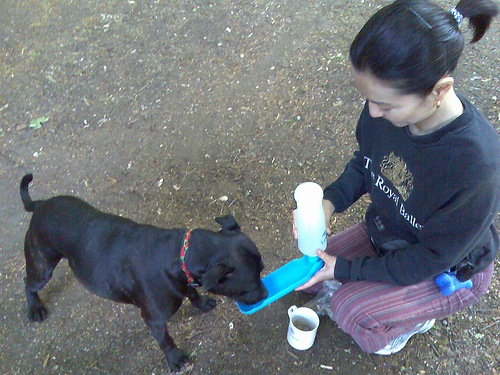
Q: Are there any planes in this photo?
A: No, there are no planes.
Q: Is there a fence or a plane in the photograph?
A: No, there are no airplanes or fences.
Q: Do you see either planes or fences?
A: No, there are no planes or fences.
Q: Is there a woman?
A: Yes, there is a woman.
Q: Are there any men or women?
A: Yes, there is a woman.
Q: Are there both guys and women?
A: No, there is a woman but no guys.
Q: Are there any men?
A: No, there are no men.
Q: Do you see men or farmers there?
A: No, there are no men or farmers.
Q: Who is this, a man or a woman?
A: This is a woman.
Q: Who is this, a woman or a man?
A: This is a woman.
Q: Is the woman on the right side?
A: Yes, the woman is on the right of the image.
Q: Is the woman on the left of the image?
A: No, the woman is on the right of the image.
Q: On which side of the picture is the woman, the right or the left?
A: The woman is on the right of the image.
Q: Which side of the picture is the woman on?
A: The woman is on the right of the image.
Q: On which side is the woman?
A: The woman is on the right of the image.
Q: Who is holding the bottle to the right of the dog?
A: The woman is holding the bottle.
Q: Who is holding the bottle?
A: The woman is holding the bottle.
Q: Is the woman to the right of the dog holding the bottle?
A: Yes, the woman is holding the bottle.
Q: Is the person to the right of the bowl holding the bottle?
A: Yes, the woman is holding the bottle.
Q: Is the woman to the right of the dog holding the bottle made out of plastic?
A: Yes, the woman is holding the bottle.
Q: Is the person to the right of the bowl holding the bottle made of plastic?
A: Yes, the woman is holding the bottle.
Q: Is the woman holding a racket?
A: No, the woman is holding the bottle.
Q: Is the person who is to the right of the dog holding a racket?
A: No, the woman is holding the bottle.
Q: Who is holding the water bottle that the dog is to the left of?
A: The woman is holding the water bottle.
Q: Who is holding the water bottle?
A: The woman is holding the water bottle.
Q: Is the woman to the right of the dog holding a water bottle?
A: Yes, the woman is holding a water bottle.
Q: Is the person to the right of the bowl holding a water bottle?
A: Yes, the woman is holding a water bottle.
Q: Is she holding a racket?
A: No, the woman is holding a water bottle.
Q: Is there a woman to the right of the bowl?
A: Yes, there is a woman to the right of the bowl.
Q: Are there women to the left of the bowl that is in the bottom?
A: No, the woman is to the right of the bowl.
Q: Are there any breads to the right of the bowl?
A: No, there is a woman to the right of the bowl.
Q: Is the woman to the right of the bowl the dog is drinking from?
A: Yes, the woman is to the right of the bowl.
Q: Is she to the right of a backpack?
A: No, the woman is to the right of the bowl.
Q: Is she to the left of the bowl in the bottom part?
A: No, the woman is to the right of the bowl.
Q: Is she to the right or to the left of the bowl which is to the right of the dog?
A: The woman is to the right of the bowl.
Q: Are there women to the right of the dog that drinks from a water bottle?
A: Yes, there is a woman to the right of the dog.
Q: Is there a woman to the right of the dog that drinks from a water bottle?
A: Yes, there is a woman to the right of the dog.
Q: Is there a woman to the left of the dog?
A: No, the woman is to the right of the dog.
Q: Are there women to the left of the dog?
A: No, the woman is to the right of the dog.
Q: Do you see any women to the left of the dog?
A: No, the woman is to the right of the dog.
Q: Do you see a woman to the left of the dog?
A: No, the woman is to the right of the dog.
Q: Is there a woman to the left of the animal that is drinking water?
A: No, the woman is to the right of the dog.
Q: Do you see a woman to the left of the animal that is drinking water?
A: No, the woman is to the right of the dog.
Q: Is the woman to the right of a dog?
A: Yes, the woman is to the right of a dog.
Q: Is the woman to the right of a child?
A: No, the woman is to the right of a dog.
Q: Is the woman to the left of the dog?
A: No, the woman is to the right of the dog.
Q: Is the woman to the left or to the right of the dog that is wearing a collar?
A: The woman is to the right of the dog.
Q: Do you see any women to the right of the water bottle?
A: Yes, there is a woman to the right of the water bottle.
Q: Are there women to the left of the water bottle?
A: No, the woman is to the right of the water bottle.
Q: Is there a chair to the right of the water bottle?
A: No, there is a woman to the right of the water bottle.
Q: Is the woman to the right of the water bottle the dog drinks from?
A: Yes, the woman is to the right of the water bottle.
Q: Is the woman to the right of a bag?
A: No, the woman is to the right of the water bottle.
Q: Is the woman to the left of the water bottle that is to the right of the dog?
A: No, the woman is to the right of the water bottle.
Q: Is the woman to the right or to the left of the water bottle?
A: The woman is to the right of the water bottle.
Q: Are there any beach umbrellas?
A: No, there are no beach umbrellas.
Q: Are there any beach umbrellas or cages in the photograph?
A: No, there are no beach umbrellas or cages.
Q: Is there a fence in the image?
A: No, there are no fences.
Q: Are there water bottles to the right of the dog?
A: Yes, there is a water bottle to the right of the dog.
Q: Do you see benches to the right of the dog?
A: No, there is a water bottle to the right of the dog.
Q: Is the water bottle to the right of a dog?
A: Yes, the water bottle is to the right of a dog.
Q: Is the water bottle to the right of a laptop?
A: No, the water bottle is to the right of a dog.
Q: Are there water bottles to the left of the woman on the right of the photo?
A: Yes, there is a water bottle to the left of the woman.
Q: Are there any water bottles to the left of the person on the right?
A: Yes, there is a water bottle to the left of the woman.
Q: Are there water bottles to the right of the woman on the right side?
A: No, the water bottle is to the left of the woman.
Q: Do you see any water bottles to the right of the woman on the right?
A: No, the water bottle is to the left of the woman.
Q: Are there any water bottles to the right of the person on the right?
A: No, the water bottle is to the left of the woman.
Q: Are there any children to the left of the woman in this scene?
A: No, there is a water bottle to the left of the woman.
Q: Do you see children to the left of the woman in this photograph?
A: No, there is a water bottle to the left of the woman.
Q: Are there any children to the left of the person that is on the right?
A: No, there is a water bottle to the left of the woman.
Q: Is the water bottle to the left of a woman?
A: Yes, the water bottle is to the left of a woman.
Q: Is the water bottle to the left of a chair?
A: No, the water bottle is to the left of a woman.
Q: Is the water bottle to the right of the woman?
A: No, the water bottle is to the left of the woman.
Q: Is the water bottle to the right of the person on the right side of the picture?
A: No, the water bottle is to the left of the woman.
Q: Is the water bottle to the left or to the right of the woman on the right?
A: The water bottle is to the left of the woman.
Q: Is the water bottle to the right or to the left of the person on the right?
A: The water bottle is to the left of the woman.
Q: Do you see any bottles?
A: Yes, there is a bottle.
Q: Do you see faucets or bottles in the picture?
A: Yes, there is a bottle.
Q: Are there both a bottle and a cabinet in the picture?
A: No, there is a bottle but no cabinets.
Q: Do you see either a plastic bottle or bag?
A: Yes, there is a plastic bottle.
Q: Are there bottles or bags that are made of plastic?
A: Yes, the bottle is made of plastic.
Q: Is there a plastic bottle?
A: Yes, there is a bottle that is made of plastic.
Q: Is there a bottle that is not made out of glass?
A: Yes, there is a bottle that is made of plastic.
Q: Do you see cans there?
A: No, there are no cans.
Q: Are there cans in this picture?
A: No, there are no cans.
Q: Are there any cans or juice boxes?
A: No, there are no cans or juice boxes.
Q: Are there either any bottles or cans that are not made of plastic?
A: No, there is a bottle but it is made of plastic.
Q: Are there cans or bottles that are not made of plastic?
A: No, there is a bottle but it is made of plastic.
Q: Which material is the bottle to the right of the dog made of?
A: The bottle is made of plastic.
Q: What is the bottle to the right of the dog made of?
A: The bottle is made of plastic.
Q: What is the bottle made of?
A: The bottle is made of plastic.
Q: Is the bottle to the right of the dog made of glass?
A: No, the bottle is made of plastic.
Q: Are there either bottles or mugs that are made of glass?
A: No, there is a bottle but it is made of plastic.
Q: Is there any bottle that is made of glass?
A: No, there is a bottle but it is made of plastic.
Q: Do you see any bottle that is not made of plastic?
A: No, there is a bottle but it is made of plastic.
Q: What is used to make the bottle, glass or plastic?
A: The bottle is made of plastic.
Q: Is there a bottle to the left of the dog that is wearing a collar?
A: No, the bottle is to the right of the dog.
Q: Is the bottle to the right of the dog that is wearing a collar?
A: Yes, the bottle is to the right of the dog.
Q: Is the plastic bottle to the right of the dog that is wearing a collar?
A: Yes, the bottle is to the right of the dog.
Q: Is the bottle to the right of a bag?
A: No, the bottle is to the right of the dog.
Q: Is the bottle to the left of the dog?
A: No, the bottle is to the right of the dog.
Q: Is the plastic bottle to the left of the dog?
A: No, the bottle is to the right of the dog.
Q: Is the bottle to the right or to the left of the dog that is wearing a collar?
A: The bottle is to the right of the dog.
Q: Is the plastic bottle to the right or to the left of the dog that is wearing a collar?
A: The bottle is to the right of the dog.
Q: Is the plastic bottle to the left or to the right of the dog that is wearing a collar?
A: The bottle is to the right of the dog.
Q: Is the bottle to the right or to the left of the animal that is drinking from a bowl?
A: The bottle is to the right of the dog.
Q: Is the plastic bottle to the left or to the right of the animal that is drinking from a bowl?
A: The bottle is to the right of the dog.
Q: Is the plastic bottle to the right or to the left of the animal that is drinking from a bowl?
A: The bottle is to the right of the dog.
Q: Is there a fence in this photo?
A: No, there are no fences.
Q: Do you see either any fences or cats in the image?
A: No, there are no fences or cats.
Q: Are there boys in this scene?
A: No, there are no boys.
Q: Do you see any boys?
A: No, there are no boys.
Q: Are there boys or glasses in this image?
A: No, there are no boys or glasses.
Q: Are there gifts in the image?
A: No, there are no gifts.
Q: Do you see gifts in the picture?
A: No, there are no gifts.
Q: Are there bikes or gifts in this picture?
A: No, there are no gifts or bikes.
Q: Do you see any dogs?
A: Yes, there is a dog.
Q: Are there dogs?
A: Yes, there is a dog.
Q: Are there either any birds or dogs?
A: Yes, there is a dog.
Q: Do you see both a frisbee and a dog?
A: No, there is a dog but no frisbees.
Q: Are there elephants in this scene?
A: No, there are no elephants.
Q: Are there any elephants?
A: No, there are no elephants.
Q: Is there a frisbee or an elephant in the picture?
A: No, there are no elephants or frisbees.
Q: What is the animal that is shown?
A: The animal is a dog.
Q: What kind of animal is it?
A: The animal is a dog.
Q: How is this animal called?
A: This is a dog.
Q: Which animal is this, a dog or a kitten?
A: This is a dog.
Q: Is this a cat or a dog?
A: This is a dog.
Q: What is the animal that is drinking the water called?
A: The animal is a dog.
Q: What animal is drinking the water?
A: The animal is a dog.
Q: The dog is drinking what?
A: The dog is drinking water.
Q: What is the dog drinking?
A: The dog is drinking water.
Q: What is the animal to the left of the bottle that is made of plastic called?
A: The animal is a dog.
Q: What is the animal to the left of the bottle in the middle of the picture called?
A: The animal is a dog.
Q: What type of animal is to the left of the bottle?
A: The animal is a dog.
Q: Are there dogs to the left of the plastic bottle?
A: Yes, there is a dog to the left of the bottle.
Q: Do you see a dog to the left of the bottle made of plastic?
A: Yes, there is a dog to the left of the bottle.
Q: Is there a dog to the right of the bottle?
A: No, the dog is to the left of the bottle.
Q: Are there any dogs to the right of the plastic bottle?
A: No, the dog is to the left of the bottle.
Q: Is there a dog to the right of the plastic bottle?
A: No, the dog is to the left of the bottle.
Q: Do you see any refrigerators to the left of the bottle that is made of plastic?
A: No, there is a dog to the left of the bottle.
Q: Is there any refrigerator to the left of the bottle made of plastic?
A: No, there is a dog to the left of the bottle.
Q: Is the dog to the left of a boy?
A: No, the dog is to the left of a bottle.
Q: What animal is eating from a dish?
A: The dog is eating from a dish.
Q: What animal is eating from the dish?
A: The dog is eating from a dish.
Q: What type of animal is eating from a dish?
A: The animal is a dog.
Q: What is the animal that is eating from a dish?
A: The animal is a dog.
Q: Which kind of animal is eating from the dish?
A: The animal is a dog.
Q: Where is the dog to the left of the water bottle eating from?
A: The dog is eating from a dish.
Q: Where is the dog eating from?
A: The dog is eating from a dish.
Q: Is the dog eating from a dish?
A: Yes, the dog is eating from a dish.